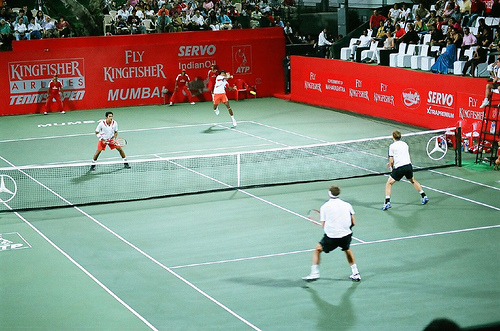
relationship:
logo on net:
[426, 135, 448, 161] [327, 142, 381, 174]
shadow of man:
[297, 277, 363, 324] [303, 186, 361, 285]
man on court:
[303, 186, 361, 285] [0, 93, 500, 327]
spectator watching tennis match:
[431, 32, 456, 77] [1, 38, 499, 327]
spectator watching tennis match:
[397, 22, 421, 45] [1, 38, 499, 327]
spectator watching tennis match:
[460, 43, 485, 72] [1, 38, 499, 327]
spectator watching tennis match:
[473, 15, 493, 47] [1, 38, 499, 327]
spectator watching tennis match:
[365, 7, 388, 32] [1, 38, 499, 327]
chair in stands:
[387, 39, 404, 66] [327, 0, 498, 77]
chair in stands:
[399, 44, 411, 66] [327, 0, 498, 77]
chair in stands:
[407, 44, 426, 67] [327, 0, 498, 77]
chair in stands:
[422, 54, 431, 69] [327, 0, 498, 77]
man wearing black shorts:
[378, 132, 433, 213] [315, 233, 355, 251]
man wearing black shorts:
[303, 186, 361, 285] [386, 164, 417, 179]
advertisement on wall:
[101, 47, 168, 82] [1, 23, 288, 118]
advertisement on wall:
[6, 54, 89, 104] [1, 23, 288, 118]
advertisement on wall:
[176, 41, 221, 73] [1, 23, 288, 118]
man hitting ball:
[212, 69, 237, 127] [250, 89, 256, 96]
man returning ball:
[201, 40, 266, 130] [229, 71, 280, 113]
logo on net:
[419, 122, 458, 173] [10, 139, 478, 182]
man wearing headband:
[305, 185, 362, 285] [304, 186, 349, 198]